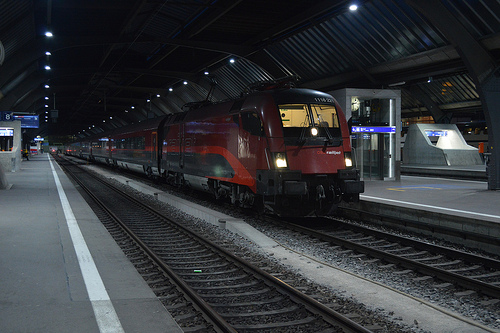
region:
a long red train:
[59, 87, 363, 209]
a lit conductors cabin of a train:
[279, 105, 338, 138]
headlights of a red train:
[273, 152, 355, 168]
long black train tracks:
[47, 151, 357, 328]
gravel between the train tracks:
[263, 225, 495, 327]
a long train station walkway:
[0, 97, 130, 328]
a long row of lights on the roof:
[42, 12, 50, 124]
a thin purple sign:
[351, 125, 398, 132]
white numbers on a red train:
[311, 96, 336, 103]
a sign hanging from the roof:
[11, 111, 38, 127]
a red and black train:
[59, 87, 365, 221]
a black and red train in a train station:
[57, 87, 365, 219]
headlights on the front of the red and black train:
[272, 156, 353, 171]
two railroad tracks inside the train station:
[139, 223, 499, 331]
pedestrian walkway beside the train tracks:
[1, 170, 130, 331]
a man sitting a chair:
[21, 150, 31, 162]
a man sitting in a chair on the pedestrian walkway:
[20, 148, 52, 170]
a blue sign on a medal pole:
[1, 110, 40, 129]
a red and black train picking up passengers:
[62, 85, 364, 221]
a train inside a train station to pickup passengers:
[52, 0, 497, 332]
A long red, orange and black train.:
[66, 85, 365, 218]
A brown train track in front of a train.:
[286, 211, 499, 293]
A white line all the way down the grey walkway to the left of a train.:
[45, 150, 122, 332]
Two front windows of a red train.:
[275, 98, 342, 133]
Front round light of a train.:
[310, 126, 319, 137]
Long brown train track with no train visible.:
[48, 150, 369, 331]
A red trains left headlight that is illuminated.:
[274, 154, 287, 169]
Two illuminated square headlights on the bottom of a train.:
[272, 153, 354, 168]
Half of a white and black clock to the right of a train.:
[350, 93, 360, 113]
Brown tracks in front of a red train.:
[285, 218, 497, 299]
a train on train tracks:
[136, 77, 407, 244]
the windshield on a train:
[261, 88, 376, 166]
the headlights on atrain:
[239, 143, 396, 203]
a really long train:
[66, 88, 331, 225]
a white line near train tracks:
[57, 155, 78, 280]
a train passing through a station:
[147, 68, 433, 218]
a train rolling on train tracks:
[127, 72, 415, 205]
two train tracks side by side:
[162, 154, 444, 299]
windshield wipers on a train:
[289, 108, 359, 156]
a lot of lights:
[33, 23, 104, 137]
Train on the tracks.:
[42, 85, 383, 235]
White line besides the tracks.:
[33, 144, 134, 331]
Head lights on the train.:
[272, 123, 355, 172]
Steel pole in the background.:
[379, 125, 396, 180]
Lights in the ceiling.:
[39, 30, 56, 127]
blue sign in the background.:
[9, 106, 43, 131]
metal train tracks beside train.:
[45, 140, 382, 329]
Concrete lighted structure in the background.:
[400, 120, 476, 170]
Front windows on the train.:
[275, 98, 343, 145]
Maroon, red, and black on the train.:
[157, 85, 369, 211]